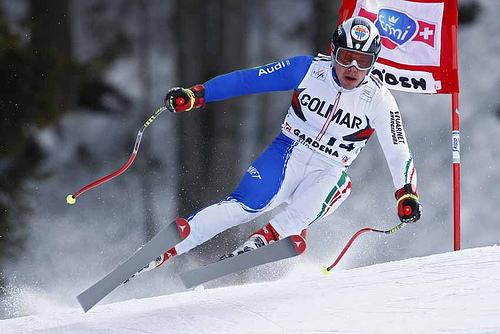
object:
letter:
[298, 95, 321, 115]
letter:
[315, 99, 334, 118]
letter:
[306, 93, 318, 111]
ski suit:
[111, 27, 462, 258]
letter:
[338, 108, 350, 129]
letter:
[348, 114, 361, 134]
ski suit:
[158, 41, 424, 255]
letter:
[282, 126, 300, 144]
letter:
[302, 129, 305, 144]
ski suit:
[139, 51, 427, 285]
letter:
[305, 136, 322, 138]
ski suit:
[193, 50, 438, 270]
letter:
[310, 137, 319, 153]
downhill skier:
[41, 16, 461, 314]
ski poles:
[39, 95, 195, 215]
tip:
[172, 213, 196, 243]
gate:
[126, 3, 471, 283]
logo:
[375, 8, 420, 51]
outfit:
[67, 18, 423, 315]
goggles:
[328, 46, 375, 71]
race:
[6, 4, 498, 331]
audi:
[259, 59, 294, 77]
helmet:
[328, 15, 388, 73]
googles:
[332, 41, 381, 71]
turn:
[50, 145, 500, 315]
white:
[297, 79, 418, 231]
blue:
[188, 55, 314, 220]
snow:
[21, 274, 493, 332]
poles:
[52, 81, 421, 281]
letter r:
[348, 112, 369, 133]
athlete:
[121, 16, 423, 295]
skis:
[179, 234, 308, 294]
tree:
[0, 14, 142, 285]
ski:
[72, 210, 317, 322]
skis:
[76, 219, 188, 317]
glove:
[165, 83, 209, 113]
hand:
[163, 91, 205, 116]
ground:
[125, 237, 232, 331]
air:
[168, 25, 259, 56]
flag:
[340, 0, 463, 254]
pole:
[451, 115, 460, 251]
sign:
[376, 1, 485, 109]